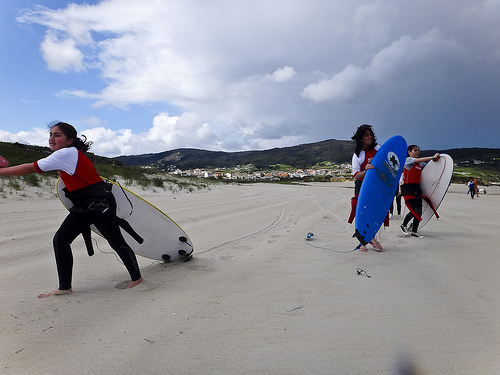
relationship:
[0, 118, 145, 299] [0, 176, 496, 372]
people on beach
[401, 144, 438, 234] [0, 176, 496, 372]
people on beach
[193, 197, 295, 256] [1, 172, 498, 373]
track in sand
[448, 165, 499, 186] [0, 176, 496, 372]
grass on beach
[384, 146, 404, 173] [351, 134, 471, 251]
symbol on board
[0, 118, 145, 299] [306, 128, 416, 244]
people dragging surfboard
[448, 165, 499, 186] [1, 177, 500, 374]
grass on sand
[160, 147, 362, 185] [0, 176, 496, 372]
grass on beach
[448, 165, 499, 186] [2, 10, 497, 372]
grass on beach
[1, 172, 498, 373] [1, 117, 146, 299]
sand under person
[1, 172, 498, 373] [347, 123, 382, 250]
sand under person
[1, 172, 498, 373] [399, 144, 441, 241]
sand under person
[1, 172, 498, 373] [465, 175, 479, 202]
sand under person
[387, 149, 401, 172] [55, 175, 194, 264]
symbol on board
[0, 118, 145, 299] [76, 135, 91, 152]
people wearing tail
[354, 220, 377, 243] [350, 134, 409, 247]
bottom of board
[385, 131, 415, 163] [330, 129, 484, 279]
top of board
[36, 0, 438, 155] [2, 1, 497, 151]
cloud in sky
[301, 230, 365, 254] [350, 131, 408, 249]
cord on surfboard